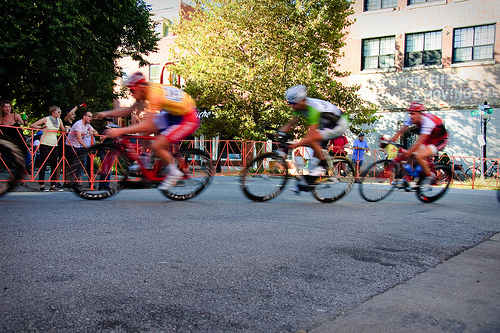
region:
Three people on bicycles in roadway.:
[26, 42, 471, 251]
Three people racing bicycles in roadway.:
[2, 39, 474, 234]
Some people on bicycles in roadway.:
[39, 25, 489, 257]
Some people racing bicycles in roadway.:
[51, 8, 461, 270]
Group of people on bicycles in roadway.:
[34, 23, 465, 254]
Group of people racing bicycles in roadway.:
[25, 36, 475, 291]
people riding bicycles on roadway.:
[30, 33, 475, 281]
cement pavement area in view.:
[36, 211, 413, 307]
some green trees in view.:
[176, 11, 326, 73]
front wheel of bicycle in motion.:
[236, 142, 289, 210]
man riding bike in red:
[351, 87, 461, 220]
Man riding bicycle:
[71, 62, 216, 200]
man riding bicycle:
[243, 79, 374, 221]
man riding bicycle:
[378, 87, 478, 211]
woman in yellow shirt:
[16, 96, 72, 179]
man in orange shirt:
[111, 60, 205, 120]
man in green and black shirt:
[278, 76, 350, 129]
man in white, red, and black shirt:
[387, 85, 464, 149]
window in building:
[350, 26, 415, 69]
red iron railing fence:
[213, 131, 259, 178]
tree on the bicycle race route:
[196, 15, 336, 181]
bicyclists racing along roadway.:
[22, 38, 470, 226]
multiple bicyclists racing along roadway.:
[17, 29, 467, 222]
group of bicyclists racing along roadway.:
[24, 36, 476, 240]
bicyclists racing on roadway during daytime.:
[37, 21, 477, 276]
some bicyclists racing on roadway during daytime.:
[20, 23, 466, 281]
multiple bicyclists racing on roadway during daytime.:
[27, 36, 474, 272]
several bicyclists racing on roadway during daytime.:
[12, 24, 474, 246]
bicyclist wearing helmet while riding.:
[237, 63, 354, 210]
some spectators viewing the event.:
[0, 74, 95, 148]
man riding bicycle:
[81, 70, 208, 207]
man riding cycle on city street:
[237, 82, 373, 221]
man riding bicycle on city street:
[361, 97, 467, 203]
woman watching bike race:
[34, 97, 66, 199]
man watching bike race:
[69, 106, 96, 181]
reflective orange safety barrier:
[4, 118, 334, 205]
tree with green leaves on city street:
[183, 3, 358, 164]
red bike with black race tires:
[79, 128, 228, 215]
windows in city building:
[360, 20, 498, 95]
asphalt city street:
[5, 157, 498, 321]